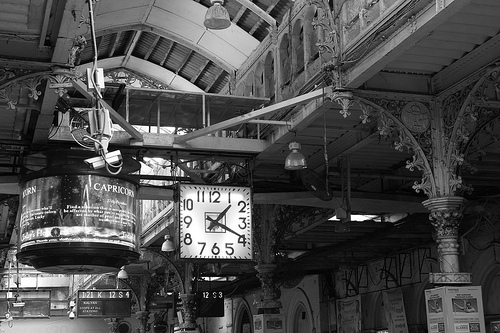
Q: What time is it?
A: 1:19.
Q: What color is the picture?
A: Black and white.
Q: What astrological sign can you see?
A: Capricorn.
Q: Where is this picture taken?
A: A station.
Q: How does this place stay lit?
A: Lights from the ceiling.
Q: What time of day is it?
A: Day time.